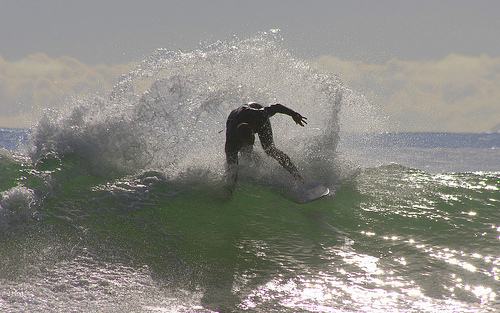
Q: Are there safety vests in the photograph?
A: No, there are no safety vests.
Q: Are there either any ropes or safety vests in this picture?
A: No, there are no safety vests or ropes.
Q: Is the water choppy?
A: Yes, the water is choppy.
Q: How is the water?
A: The water is choppy.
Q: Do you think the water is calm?
A: No, the water is choppy.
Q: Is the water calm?
A: No, the water is choppy.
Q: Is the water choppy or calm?
A: The water is choppy.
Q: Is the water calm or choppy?
A: The water is choppy.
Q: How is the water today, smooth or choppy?
A: The water is choppy.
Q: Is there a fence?
A: No, there are no fences.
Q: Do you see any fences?
A: No, there are no fences.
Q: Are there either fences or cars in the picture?
A: No, there are no fences or cars.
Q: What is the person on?
A: The person is on the surf board.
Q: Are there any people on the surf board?
A: Yes, there is a person on the surf board.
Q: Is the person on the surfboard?
A: Yes, the person is on the surfboard.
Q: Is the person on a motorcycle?
A: No, the person is on the surfboard.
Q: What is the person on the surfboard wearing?
A: The person is wearing a wet suit.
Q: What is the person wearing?
A: The person is wearing a wet suit.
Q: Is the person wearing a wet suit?
A: Yes, the person is wearing a wet suit.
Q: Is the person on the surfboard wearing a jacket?
A: No, the person is wearing a wet suit.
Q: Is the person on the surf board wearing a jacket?
A: No, the person is wearing a wet suit.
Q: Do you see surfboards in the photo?
A: Yes, there is a surfboard.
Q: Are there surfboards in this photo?
A: Yes, there is a surfboard.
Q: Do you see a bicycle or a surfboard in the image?
A: Yes, there is a surfboard.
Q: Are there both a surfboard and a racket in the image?
A: No, there is a surfboard but no rackets.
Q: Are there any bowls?
A: No, there are no bowls.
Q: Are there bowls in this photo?
A: No, there are no bowls.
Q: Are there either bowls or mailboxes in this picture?
A: No, there are no bowls or mailboxes.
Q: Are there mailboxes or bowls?
A: No, there are no bowls or mailboxes.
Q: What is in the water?
A: The surfboard is in the water.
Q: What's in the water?
A: The surfboard is in the water.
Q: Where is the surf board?
A: The surf board is in the water.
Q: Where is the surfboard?
A: The surf board is in the water.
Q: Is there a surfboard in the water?
A: Yes, there is a surfboard in the water.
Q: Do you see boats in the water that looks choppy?
A: No, there is a surfboard in the water.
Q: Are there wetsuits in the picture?
A: Yes, there is a wetsuit.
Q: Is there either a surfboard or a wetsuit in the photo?
A: Yes, there is a wetsuit.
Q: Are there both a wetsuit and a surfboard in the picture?
A: Yes, there are both a wetsuit and a surfboard.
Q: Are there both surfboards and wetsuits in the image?
A: Yes, there are both a wetsuit and a surfboard.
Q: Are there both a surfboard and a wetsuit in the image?
A: Yes, there are both a wetsuit and a surfboard.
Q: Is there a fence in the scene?
A: No, there are no fences.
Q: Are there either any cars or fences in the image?
A: No, there are no fences or cars.